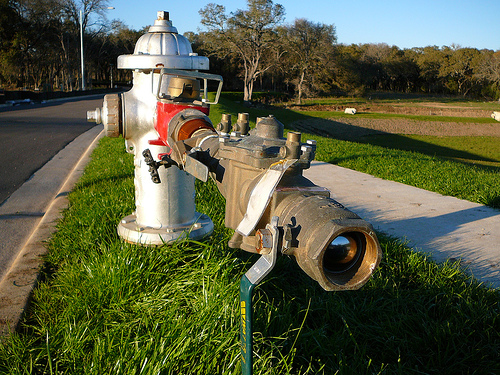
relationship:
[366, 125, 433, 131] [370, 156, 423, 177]
dirt in grass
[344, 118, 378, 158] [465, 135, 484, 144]
shadow on ground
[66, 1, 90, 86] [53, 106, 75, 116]
lamp across road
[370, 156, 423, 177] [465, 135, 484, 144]
grass on ground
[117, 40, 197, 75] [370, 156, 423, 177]
hydrant in grass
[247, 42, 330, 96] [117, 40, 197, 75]
trees behind hydrant